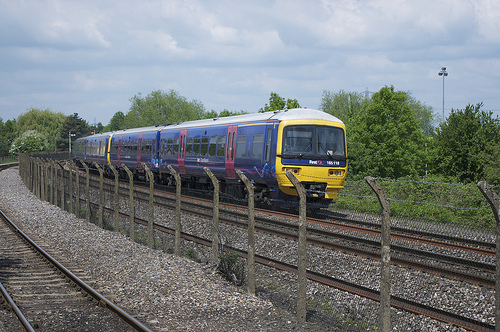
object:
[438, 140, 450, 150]
leaves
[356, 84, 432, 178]
tree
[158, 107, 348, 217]
car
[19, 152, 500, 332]
fencing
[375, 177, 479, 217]
barbwire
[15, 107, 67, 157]
trees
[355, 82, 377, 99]
frame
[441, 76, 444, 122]
pole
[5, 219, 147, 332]
tracks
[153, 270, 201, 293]
stones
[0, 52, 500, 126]
skies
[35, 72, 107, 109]
clouds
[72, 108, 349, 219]
train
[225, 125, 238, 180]
doors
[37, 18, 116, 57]
clouds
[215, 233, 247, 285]
weeds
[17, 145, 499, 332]
line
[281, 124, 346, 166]
windshield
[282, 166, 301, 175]
headlights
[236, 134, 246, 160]
car window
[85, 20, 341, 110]
sky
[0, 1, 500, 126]
sky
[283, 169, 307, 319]
post